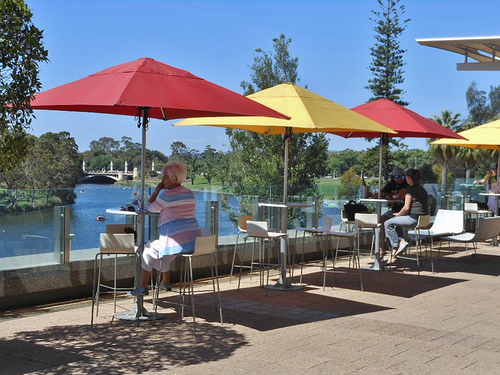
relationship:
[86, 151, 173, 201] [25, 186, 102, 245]
bridge over water